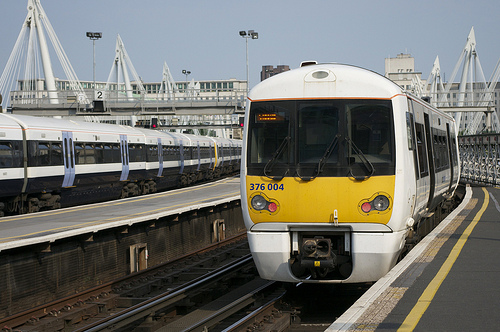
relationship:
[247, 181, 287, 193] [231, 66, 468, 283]
number on train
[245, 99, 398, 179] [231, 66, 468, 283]
windshield on train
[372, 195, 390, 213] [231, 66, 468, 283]
light on train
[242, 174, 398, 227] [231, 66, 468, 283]
strip on train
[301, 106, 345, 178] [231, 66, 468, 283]
window on railroad car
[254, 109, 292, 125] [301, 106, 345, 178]
sign in window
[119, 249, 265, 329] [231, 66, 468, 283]
track for train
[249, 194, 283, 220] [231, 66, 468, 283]
headlight on train